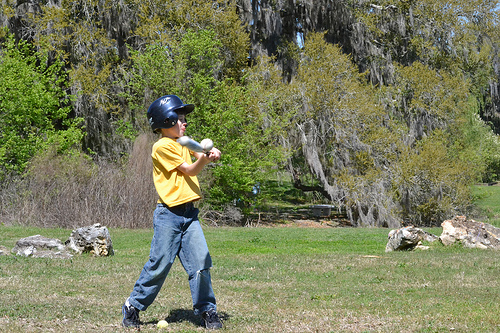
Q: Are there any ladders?
A: No, there are no ladders.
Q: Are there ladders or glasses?
A: No, there are no ladders or glasses.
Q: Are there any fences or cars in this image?
A: No, there are no cars or fences.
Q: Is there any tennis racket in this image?
A: No, there are no rackets.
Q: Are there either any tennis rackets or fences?
A: No, there are no tennis rackets or fences.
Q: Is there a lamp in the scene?
A: No, there are no lamps.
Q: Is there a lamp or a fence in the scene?
A: No, there are no lamps or fences.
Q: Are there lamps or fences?
A: No, there are no lamps or fences.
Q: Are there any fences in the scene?
A: No, there are no fences.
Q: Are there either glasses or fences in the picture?
A: No, there are no fences or glasses.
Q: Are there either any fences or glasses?
A: No, there are no fences or glasses.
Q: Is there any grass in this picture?
A: Yes, there is grass.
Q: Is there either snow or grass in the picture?
A: Yes, there is grass.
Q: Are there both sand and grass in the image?
A: No, there is grass but no sand.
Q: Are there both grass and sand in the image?
A: No, there is grass but no sand.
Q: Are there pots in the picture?
A: No, there are no pots.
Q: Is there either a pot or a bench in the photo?
A: No, there are no pots or benches.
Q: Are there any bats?
A: Yes, there is a bat.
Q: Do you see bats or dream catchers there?
A: Yes, there is a bat.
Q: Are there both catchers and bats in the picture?
A: No, there is a bat but no catchers.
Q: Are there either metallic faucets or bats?
A: Yes, there is a metal bat.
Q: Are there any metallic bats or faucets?
A: Yes, there is a metal bat.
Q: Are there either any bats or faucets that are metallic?
A: Yes, the bat is metallic.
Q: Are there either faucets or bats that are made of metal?
A: Yes, the bat is made of metal.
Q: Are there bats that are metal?
A: Yes, there is a metal bat.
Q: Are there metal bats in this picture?
A: Yes, there is a metal bat.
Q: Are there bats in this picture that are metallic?
A: Yes, there is a bat that is metallic.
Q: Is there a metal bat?
A: Yes, there is a bat that is made of metal.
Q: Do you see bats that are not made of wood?
A: Yes, there is a bat that is made of metal.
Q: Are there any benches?
A: No, there are no benches.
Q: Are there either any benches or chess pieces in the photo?
A: No, there are no benches or chess pieces.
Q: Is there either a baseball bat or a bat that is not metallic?
A: No, there is a bat but it is metallic.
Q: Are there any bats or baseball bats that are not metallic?
A: No, there is a bat but it is metallic.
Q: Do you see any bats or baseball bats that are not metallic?
A: No, there is a bat but it is metallic.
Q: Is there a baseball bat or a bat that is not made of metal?
A: No, there is a bat but it is made of metal.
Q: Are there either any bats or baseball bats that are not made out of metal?
A: No, there is a bat but it is made of metal.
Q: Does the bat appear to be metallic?
A: Yes, the bat is metallic.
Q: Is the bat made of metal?
A: Yes, the bat is made of metal.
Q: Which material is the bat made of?
A: The bat is made of metal.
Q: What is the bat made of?
A: The bat is made of metal.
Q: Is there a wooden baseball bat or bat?
A: No, there is a bat but it is metallic.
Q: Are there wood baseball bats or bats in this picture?
A: No, there is a bat but it is metallic.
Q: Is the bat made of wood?
A: No, the bat is made of metal.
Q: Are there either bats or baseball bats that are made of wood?
A: No, there is a bat but it is made of metal.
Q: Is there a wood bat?
A: No, there is a bat but it is made of metal.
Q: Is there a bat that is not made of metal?
A: No, there is a bat but it is made of metal.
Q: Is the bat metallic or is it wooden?
A: The bat is metallic.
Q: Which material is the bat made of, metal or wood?
A: The bat is made of metal.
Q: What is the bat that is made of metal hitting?
A: The bat is hitting the ball.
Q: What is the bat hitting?
A: The bat is hitting the ball.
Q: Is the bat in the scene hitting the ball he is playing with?
A: Yes, the bat is hitting the ball.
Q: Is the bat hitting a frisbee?
A: No, the bat is hitting the ball.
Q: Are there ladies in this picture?
A: No, there are no ladies.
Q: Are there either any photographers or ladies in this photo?
A: No, there are no ladies or photographers.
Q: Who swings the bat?
A: The boy swings the bat.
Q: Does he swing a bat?
A: Yes, the boy swings a bat.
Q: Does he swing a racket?
A: No, the boy swings a bat.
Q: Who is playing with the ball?
A: The boy is playing with the ball.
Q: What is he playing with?
A: The boy is playing with a ball.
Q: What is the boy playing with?
A: The boy is playing with a ball.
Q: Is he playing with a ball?
A: Yes, the boy is playing with a ball.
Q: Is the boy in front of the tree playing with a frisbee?
A: No, the boy is playing with a ball.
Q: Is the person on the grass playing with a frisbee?
A: No, the boy is playing with a ball.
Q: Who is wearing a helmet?
A: The boy is wearing a helmet.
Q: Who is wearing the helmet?
A: The boy is wearing a helmet.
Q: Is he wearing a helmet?
A: Yes, the boy is wearing a helmet.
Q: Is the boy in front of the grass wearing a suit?
A: No, the boy is wearing a helmet.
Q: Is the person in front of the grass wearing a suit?
A: No, the boy is wearing a helmet.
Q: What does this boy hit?
A: The boy hits the ball.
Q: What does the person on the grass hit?
A: The boy hits the ball.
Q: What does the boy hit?
A: The boy hits the ball.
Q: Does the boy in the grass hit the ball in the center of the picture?
A: Yes, the boy hits the ball.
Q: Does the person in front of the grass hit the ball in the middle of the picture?
A: Yes, the boy hits the ball.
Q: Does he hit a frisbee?
A: No, the boy hits the ball.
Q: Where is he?
A: The boy is in the grass.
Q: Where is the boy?
A: The boy is in the grass.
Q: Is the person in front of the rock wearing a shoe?
A: Yes, the boy is wearing a shoe.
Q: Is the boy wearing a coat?
A: No, the boy is wearing a shoe.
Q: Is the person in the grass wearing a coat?
A: No, the boy is wearing a shoe.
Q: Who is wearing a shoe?
A: The boy is wearing a shoe.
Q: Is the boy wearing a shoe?
A: Yes, the boy is wearing a shoe.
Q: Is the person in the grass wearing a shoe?
A: Yes, the boy is wearing a shoe.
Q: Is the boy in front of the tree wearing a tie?
A: No, the boy is wearing a shoe.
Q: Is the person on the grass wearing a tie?
A: No, the boy is wearing a shoe.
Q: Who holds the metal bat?
A: The boy holds the bat.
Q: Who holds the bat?
A: The boy holds the bat.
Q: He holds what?
A: The boy holds the bat.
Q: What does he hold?
A: The boy holds the bat.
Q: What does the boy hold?
A: The boy holds the bat.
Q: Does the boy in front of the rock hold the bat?
A: Yes, the boy holds the bat.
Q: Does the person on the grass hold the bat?
A: Yes, the boy holds the bat.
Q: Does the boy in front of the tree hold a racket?
A: No, the boy holds the bat.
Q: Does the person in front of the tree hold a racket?
A: No, the boy holds the bat.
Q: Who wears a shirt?
A: The boy wears a shirt.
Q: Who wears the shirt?
A: The boy wears a shirt.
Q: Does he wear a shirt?
A: Yes, the boy wears a shirt.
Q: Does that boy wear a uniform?
A: No, the boy wears a shirt.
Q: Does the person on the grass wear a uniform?
A: No, the boy wears a shirt.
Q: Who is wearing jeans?
A: The boy is wearing jeans.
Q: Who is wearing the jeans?
A: The boy is wearing jeans.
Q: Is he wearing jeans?
A: Yes, the boy is wearing jeans.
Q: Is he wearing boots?
A: No, the boy is wearing jeans.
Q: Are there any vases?
A: No, there are no vases.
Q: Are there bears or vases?
A: No, there are no vases or bears.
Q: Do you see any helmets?
A: Yes, there is a helmet.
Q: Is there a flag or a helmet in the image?
A: Yes, there is a helmet.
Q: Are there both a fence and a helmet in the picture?
A: No, there is a helmet but no fences.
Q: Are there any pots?
A: No, there are no pots.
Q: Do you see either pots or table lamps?
A: No, there are no pots or table lamps.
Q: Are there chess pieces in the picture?
A: No, there are no chess pieces.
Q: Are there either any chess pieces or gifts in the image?
A: No, there are no chess pieces or gifts.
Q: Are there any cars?
A: No, there are no cars.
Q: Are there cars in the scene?
A: No, there are no cars.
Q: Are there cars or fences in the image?
A: No, there are no cars or fences.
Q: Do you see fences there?
A: No, there are no fences.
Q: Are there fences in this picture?
A: No, there are no fences.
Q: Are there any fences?
A: No, there are no fences.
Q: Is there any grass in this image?
A: Yes, there is grass.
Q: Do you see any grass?
A: Yes, there is grass.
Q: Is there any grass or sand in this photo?
A: Yes, there is grass.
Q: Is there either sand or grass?
A: Yes, there is grass.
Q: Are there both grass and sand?
A: No, there is grass but no sand.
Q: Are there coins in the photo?
A: No, there are no coins.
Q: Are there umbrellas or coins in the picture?
A: No, there are no coins or umbrellas.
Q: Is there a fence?
A: No, there are no fences.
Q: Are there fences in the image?
A: No, there are no fences.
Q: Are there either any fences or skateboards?
A: No, there are no fences or skateboards.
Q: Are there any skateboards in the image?
A: No, there are no skateboards.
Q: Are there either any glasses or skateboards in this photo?
A: No, there are no skateboards or glasses.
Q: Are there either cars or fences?
A: No, there are no cars or fences.